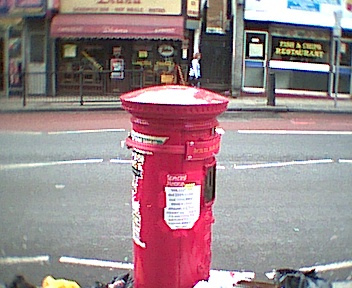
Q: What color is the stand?
A: Red.